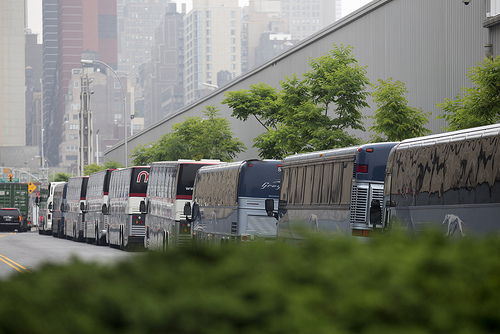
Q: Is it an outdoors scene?
A: Yes, it is outdoors.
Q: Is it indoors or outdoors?
A: It is outdoors.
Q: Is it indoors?
A: No, it is outdoors.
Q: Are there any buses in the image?
A: Yes, there is a bus.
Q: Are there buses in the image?
A: Yes, there is a bus.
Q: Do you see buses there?
A: Yes, there is a bus.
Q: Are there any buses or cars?
A: Yes, there is a bus.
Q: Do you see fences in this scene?
A: No, there are no fences.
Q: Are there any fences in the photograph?
A: No, there are no fences.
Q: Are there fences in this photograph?
A: No, there are no fences.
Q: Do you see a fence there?
A: No, there are no fences.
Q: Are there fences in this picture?
A: No, there are no fences.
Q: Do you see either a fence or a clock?
A: No, there are no fences or clocks.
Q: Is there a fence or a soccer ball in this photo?
A: No, there are no fences or soccer balls.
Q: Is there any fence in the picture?
A: No, there are no fences.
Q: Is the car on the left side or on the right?
A: The car is on the left of the image.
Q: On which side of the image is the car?
A: The car is on the left of the image.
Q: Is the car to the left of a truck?
A: No, the car is to the left of a bus.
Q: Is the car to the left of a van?
A: No, the car is to the left of a bus.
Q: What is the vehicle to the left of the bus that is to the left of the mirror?
A: The vehicle is a car.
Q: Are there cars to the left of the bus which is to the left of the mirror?
A: Yes, there is a car to the left of the bus.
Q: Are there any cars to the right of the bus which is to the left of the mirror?
A: No, the car is to the left of the bus.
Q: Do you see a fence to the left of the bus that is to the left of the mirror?
A: No, there is a car to the left of the bus.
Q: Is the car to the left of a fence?
A: No, the car is to the left of the bus.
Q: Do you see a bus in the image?
A: Yes, there is a bus.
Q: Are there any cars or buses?
A: Yes, there is a bus.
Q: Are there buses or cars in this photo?
A: Yes, there is a bus.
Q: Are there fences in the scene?
A: No, there are no fences.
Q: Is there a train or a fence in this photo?
A: No, there are no fences or trains.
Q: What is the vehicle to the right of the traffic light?
A: The vehicle is a bus.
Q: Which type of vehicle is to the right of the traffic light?
A: The vehicle is a bus.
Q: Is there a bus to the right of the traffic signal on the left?
A: Yes, there is a bus to the right of the traffic light.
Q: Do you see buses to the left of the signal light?
A: No, the bus is to the right of the signal light.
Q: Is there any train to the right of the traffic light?
A: No, there is a bus to the right of the traffic light.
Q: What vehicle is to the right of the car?
A: The vehicle is a bus.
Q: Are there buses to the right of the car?
A: Yes, there is a bus to the right of the car.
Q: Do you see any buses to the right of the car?
A: Yes, there is a bus to the right of the car.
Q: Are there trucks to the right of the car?
A: No, there is a bus to the right of the car.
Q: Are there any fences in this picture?
A: No, there are no fences.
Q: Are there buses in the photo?
A: Yes, there is a bus.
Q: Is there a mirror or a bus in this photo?
A: Yes, there is a bus.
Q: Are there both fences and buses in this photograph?
A: No, there is a bus but no fences.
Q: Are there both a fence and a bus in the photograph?
A: No, there is a bus but no fences.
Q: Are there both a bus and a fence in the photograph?
A: No, there is a bus but no fences.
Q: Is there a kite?
A: No, there are no kites.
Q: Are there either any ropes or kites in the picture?
A: No, there are no kites or ropes.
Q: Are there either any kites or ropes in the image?
A: No, there are no kites or ropes.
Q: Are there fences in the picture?
A: No, there are no fences.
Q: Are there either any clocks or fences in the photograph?
A: No, there are no fences or clocks.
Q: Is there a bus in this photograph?
A: Yes, there is a bus.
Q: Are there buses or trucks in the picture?
A: Yes, there is a bus.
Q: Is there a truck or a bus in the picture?
A: Yes, there is a bus.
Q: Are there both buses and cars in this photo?
A: Yes, there are both a bus and a car.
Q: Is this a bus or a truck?
A: This is a bus.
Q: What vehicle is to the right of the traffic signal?
A: The vehicle is a bus.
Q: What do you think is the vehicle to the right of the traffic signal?
A: The vehicle is a bus.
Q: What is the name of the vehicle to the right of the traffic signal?
A: The vehicle is a bus.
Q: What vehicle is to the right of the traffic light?
A: The vehicle is a bus.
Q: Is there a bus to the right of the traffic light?
A: Yes, there is a bus to the right of the traffic light.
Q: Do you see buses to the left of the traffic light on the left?
A: No, the bus is to the right of the traffic signal.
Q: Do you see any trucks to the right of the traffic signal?
A: No, there is a bus to the right of the traffic signal.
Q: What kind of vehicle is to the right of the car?
A: The vehicle is a bus.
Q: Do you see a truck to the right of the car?
A: No, there is a bus to the right of the car.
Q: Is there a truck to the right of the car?
A: No, there is a bus to the right of the car.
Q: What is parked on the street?
A: The bus is parked on the street.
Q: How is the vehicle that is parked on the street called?
A: The vehicle is a bus.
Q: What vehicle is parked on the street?
A: The vehicle is a bus.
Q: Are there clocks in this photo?
A: No, there are no clocks.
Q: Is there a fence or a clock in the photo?
A: No, there are no clocks or fences.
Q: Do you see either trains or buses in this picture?
A: Yes, there is a bus.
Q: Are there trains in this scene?
A: No, there are no trains.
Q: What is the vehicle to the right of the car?
A: The vehicle is a bus.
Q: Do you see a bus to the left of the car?
A: No, the bus is to the right of the car.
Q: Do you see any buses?
A: Yes, there is a bus.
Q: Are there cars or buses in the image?
A: Yes, there is a bus.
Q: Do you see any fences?
A: No, there are no fences.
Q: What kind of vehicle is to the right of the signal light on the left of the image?
A: The vehicle is a bus.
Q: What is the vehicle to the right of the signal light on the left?
A: The vehicle is a bus.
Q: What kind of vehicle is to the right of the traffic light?
A: The vehicle is a bus.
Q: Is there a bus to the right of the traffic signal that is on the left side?
A: Yes, there is a bus to the right of the traffic light.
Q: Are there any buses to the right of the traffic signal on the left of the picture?
A: Yes, there is a bus to the right of the traffic light.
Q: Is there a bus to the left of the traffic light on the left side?
A: No, the bus is to the right of the traffic signal.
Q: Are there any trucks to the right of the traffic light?
A: No, there is a bus to the right of the traffic light.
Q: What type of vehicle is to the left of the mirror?
A: The vehicle is a bus.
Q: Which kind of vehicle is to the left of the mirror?
A: The vehicle is a bus.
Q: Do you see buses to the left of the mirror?
A: Yes, there is a bus to the left of the mirror.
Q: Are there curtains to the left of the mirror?
A: No, there is a bus to the left of the mirror.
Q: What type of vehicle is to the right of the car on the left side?
A: The vehicle is a bus.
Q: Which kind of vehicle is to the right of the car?
A: The vehicle is a bus.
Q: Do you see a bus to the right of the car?
A: Yes, there is a bus to the right of the car.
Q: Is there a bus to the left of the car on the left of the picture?
A: No, the bus is to the right of the car.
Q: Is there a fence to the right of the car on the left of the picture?
A: No, there is a bus to the right of the car.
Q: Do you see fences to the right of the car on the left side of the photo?
A: No, there is a bus to the right of the car.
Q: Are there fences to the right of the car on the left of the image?
A: No, there is a bus to the right of the car.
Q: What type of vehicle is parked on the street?
A: The vehicle is a bus.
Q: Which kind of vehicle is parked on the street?
A: The vehicle is a bus.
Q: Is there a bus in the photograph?
A: Yes, there is a bus.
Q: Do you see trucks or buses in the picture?
A: Yes, there is a bus.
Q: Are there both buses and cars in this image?
A: Yes, there are both a bus and a car.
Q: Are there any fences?
A: No, there are no fences.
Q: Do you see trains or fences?
A: No, there are no fences or trains.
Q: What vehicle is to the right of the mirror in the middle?
A: The vehicle is a bus.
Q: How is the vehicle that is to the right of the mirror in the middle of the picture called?
A: The vehicle is a bus.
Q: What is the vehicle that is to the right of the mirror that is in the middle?
A: The vehicle is a bus.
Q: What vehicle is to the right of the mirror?
A: The vehicle is a bus.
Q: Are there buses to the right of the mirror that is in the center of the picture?
A: Yes, there is a bus to the right of the mirror.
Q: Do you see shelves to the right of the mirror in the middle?
A: No, there is a bus to the right of the mirror.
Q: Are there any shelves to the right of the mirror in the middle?
A: No, there is a bus to the right of the mirror.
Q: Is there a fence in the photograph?
A: No, there are no fences.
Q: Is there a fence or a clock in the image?
A: No, there are no fences or clocks.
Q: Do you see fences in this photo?
A: No, there are no fences.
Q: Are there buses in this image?
A: Yes, there is a bus.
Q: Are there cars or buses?
A: Yes, there is a bus.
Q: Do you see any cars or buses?
A: Yes, there is a bus.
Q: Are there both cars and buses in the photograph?
A: Yes, there are both a bus and a car.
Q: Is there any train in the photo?
A: No, there are no trains.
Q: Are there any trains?
A: No, there are no trains.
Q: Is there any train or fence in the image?
A: No, there are no trains or fences.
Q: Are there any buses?
A: Yes, there is a bus.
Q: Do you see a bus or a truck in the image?
A: Yes, there is a bus.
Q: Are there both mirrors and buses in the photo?
A: Yes, there are both a bus and a mirror.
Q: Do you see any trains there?
A: No, there are no trains.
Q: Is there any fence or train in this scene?
A: No, there are no trains or fences.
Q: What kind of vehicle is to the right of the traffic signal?
A: The vehicle is a bus.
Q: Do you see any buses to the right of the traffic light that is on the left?
A: Yes, there is a bus to the right of the signal light.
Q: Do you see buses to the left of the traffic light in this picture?
A: No, the bus is to the right of the traffic light.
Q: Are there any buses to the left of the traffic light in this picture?
A: No, the bus is to the right of the traffic light.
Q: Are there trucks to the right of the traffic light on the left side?
A: No, there is a bus to the right of the traffic signal.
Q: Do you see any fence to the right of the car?
A: No, there is a bus to the right of the car.